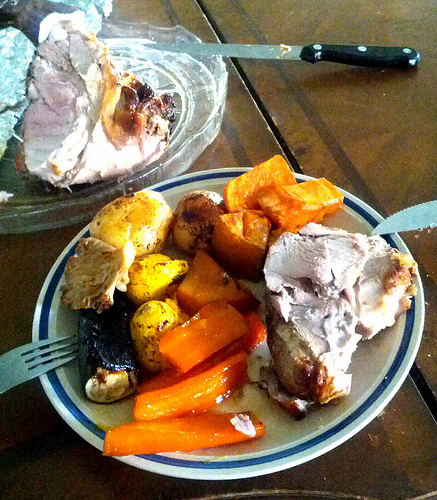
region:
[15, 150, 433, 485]
dish is white and blue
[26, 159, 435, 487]
dish has a blue border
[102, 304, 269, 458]
slices of carrots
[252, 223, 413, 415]
piece of white meat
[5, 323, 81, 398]
fork leans on dish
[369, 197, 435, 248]
tip of a knife is silver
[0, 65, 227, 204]
piece of meat is on a container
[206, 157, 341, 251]
sweet potato next to meat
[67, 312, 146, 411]
piece of zucchini in the dish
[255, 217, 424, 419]
meat of chicken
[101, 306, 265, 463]
carrot slices on a plate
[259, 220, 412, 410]
a chunk of meat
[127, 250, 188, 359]
two dollops of yellow stuff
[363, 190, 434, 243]
the end of a steak knife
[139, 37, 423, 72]
steak knife on a table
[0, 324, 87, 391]
fork laying on the plate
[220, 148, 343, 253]
chunks of sweet potato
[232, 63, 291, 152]
gap in the table top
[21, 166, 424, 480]
white plate with blue trim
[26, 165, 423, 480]
blue circle at edge of plate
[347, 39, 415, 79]
handle of the knife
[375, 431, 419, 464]
table below the plate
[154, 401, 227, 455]
orange slice on food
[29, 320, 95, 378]
fork next to the plate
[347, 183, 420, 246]
knife next to the plate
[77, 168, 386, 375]
many pieces of food on the plate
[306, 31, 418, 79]
three circles on the knife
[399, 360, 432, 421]
line on the table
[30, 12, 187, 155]
eaten food on the plate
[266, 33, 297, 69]
food on the knife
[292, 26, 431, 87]
knife handle is black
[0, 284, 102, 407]
fork is on edge of plate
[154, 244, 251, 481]
the food is orange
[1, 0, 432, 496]
the surface is green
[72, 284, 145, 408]
meat has been cut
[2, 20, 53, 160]
aluminum foil next to meat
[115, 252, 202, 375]
the food is yellow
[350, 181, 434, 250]
knife next to meat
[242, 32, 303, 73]
meat pieces on knife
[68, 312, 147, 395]
meat has been grilled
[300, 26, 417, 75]
black handle of knife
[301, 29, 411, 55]
silver rivets on knife handle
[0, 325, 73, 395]
silver metal fork laying on plate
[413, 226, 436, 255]
food crumbs on wooden table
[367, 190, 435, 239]
serrated knife blade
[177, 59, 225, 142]
clear plastic container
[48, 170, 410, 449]
cooked food on white dinner plate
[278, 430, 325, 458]
blue stripe around edge of plate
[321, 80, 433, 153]
wooden table top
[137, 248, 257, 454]
cooked sweet potatoes on plate